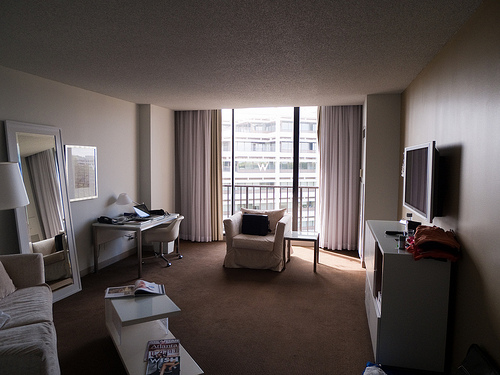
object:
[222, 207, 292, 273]
chair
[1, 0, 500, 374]
room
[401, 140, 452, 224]
tv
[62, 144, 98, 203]
picture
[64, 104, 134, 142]
wall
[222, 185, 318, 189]
rail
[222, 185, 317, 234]
balcony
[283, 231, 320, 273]
table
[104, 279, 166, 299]
magazine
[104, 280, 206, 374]
coffee table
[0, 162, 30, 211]
lamp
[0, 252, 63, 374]
chair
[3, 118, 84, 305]
mirror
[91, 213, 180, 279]
table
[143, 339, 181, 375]
magazine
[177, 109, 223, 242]
curtain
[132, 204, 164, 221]
laptop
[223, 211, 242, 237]
arm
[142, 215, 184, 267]
chair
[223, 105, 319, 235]
door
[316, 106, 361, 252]
curtain